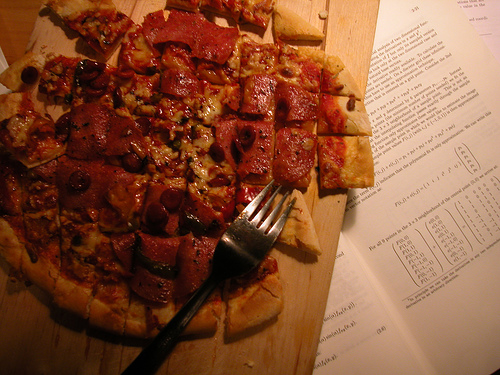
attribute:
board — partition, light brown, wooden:
[0, 1, 381, 374]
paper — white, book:
[312, 2, 499, 374]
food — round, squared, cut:
[1, 3, 375, 334]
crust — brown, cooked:
[275, 14, 378, 187]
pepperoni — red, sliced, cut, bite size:
[65, 103, 149, 161]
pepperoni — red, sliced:
[215, 116, 274, 172]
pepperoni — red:
[155, 8, 240, 65]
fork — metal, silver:
[117, 180, 298, 374]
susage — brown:
[118, 92, 159, 119]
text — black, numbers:
[313, 5, 499, 370]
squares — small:
[318, 135, 376, 190]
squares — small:
[70, 57, 118, 109]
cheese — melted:
[11, 0, 304, 297]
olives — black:
[69, 170, 93, 192]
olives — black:
[240, 124, 257, 145]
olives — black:
[160, 188, 182, 211]